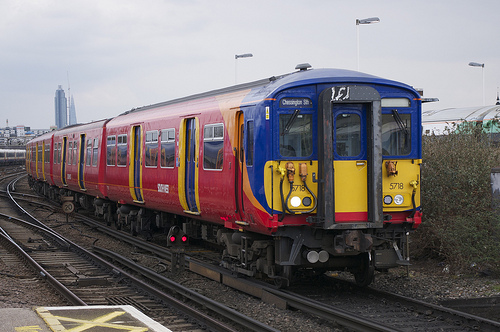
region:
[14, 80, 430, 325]
the train is blue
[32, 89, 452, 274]
the train is red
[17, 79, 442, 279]
the train is yellow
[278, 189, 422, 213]
the train has headlights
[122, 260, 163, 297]
the tracks are metal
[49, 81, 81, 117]
the buildings are high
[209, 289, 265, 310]
the gravel is gray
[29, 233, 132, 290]
the train is beside the tracks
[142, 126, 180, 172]
the windows are on the train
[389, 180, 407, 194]
the numbers are black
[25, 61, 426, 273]
Red, blue, yellow and orange train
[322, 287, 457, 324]
Train tracks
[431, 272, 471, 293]
Gravel around train tracks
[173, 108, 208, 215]
Blue door on side of train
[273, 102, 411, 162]
Front windows on train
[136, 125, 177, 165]
Side windows on a train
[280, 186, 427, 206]
Headlights on front of train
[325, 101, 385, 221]
Door on front of train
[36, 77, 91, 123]
Tall building in the distance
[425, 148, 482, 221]
Bushes near train tracks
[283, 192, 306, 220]
a train's headlight.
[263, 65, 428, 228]
the front of a moving train.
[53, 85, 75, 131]
a very tall building.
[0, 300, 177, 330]
a painted loading platform.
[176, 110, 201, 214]
an entrance to a train.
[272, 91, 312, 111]
writing on the front of a train.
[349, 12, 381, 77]
a flag flying in the sky.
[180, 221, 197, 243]
a light on a train.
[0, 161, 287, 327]
a set of train tracks.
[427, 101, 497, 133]
a structure near a train.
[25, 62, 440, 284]
a colorful train car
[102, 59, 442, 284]
a red, yellow and blue train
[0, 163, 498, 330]
brown rusty train tracks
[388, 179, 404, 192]
black numbers on the train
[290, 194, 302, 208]
a bright yellow light on the train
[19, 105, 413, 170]
windows on the train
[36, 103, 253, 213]
doors on the side of the train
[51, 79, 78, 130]
a tall building in the background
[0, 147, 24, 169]
a white train in background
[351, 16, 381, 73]
a tall light pole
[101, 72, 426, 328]
the train is blue and red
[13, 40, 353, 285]
the train is blue and red